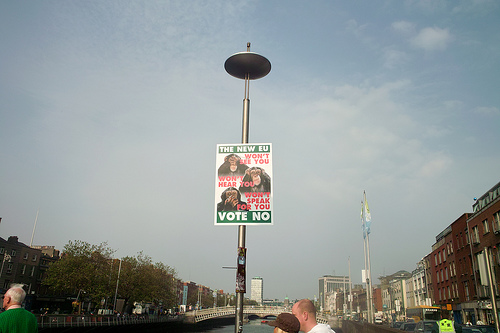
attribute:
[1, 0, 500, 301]
sky — clear, hazy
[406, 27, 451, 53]
cloud — white, small, thick, wispy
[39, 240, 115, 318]
tree — green, in background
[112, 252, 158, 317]
tree — green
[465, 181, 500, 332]
building — here, brown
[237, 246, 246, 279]
light — street light, metal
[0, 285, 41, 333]
man — older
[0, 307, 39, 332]
sweater — green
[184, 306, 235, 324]
bridge — metallic, small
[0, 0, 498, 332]
scene — city scene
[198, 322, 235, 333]
river — calm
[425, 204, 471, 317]
building — old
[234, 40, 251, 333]
pole — large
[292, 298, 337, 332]
man — balding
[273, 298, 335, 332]
couple — walking, married